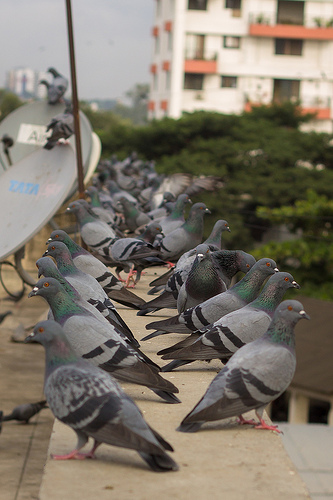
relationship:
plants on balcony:
[254, 12, 331, 31] [251, 22, 332, 38]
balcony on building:
[251, 22, 332, 38] [144, 1, 331, 123]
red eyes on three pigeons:
[262, 258, 295, 318] [143, 255, 305, 445]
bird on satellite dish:
[41, 100, 97, 150] [2, 96, 92, 235]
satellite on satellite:
[0, 96, 91, 287] [19, 164, 58, 228]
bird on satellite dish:
[41, 103, 77, 150] [0, 96, 94, 264]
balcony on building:
[183, 56, 218, 73] [144, 1, 331, 123]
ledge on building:
[36, 168, 309, 498] [0, 189, 331, 498]